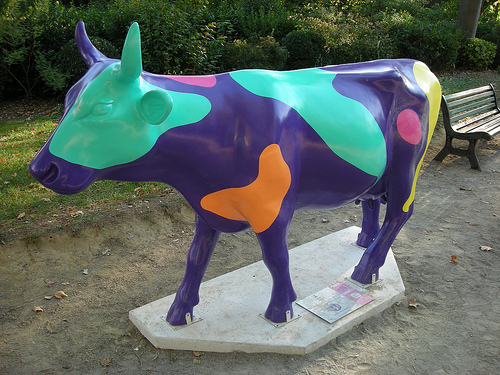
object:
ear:
[73, 16, 96, 62]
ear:
[111, 16, 151, 73]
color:
[189, 139, 214, 152]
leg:
[354, 200, 416, 290]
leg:
[357, 199, 380, 246]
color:
[416, 62, 439, 83]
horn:
[115, 19, 150, 77]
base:
[113, 221, 415, 352]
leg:
[166, 225, 231, 327]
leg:
[258, 210, 304, 330]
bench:
[439, 81, 499, 164]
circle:
[162, 66, 219, 96]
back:
[139, 69, 169, 88]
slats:
[443, 88, 495, 123]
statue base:
[124, 214, 409, 366]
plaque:
[353, 263, 395, 303]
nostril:
[37, 159, 64, 186]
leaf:
[46, 287, 71, 303]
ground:
[2, 239, 125, 355]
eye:
[87, 97, 117, 122]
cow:
[17, 4, 460, 329]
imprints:
[2, 350, 26, 367]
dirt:
[8, 286, 53, 316]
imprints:
[12, 264, 35, 284]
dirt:
[107, 340, 127, 360]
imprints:
[93, 230, 143, 255]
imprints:
[146, 250, 169, 264]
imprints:
[79, 312, 100, 322]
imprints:
[159, 355, 191, 367]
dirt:
[317, 348, 340, 373]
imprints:
[330, 343, 353, 357]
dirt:
[462, 350, 488, 373]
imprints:
[377, 318, 418, 337]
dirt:
[480, 343, 494, 372]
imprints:
[443, 314, 466, 328]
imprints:
[445, 253, 466, 270]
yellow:
[422, 67, 440, 108]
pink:
[397, 116, 418, 136]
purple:
[204, 133, 231, 160]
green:
[68, 94, 149, 161]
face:
[21, 60, 142, 181]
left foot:
[164, 302, 198, 325]